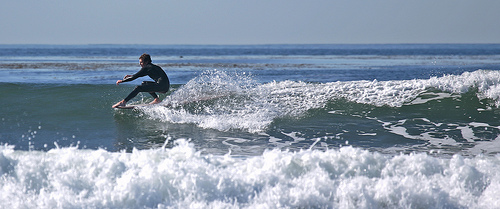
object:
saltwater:
[0, 43, 500, 208]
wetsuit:
[120, 63, 171, 102]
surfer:
[110, 52, 169, 109]